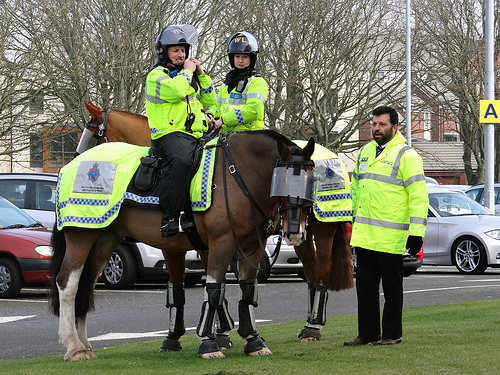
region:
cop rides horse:
[145, 19, 213, 237]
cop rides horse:
[220, 28, 269, 135]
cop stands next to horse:
[345, 106, 427, 346]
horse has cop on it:
[48, 127, 318, 360]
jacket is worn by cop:
[346, 132, 429, 257]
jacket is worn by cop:
[145, 62, 213, 139]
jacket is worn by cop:
[213, 73, 267, 131]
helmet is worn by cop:
[223, 27, 255, 71]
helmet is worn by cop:
[155, 23, 196, 66]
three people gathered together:
[83, 22, 454, 329]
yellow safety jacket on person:
[338, 130, 423, 245]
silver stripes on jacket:
[378, 150, 428, 194]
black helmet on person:
[226, 28, 261, 54]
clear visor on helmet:
[173, 28, 200, 43]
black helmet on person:
[146, 22, 191, 60]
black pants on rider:
[138, 127, 197, 219]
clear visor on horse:
[256, 161, 318, 209]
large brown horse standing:
[33, 133, 319, 362]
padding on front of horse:
[190, 276, 274, 357]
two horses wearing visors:
[41, 97, 355, 367]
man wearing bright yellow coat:
[341, 105, 433, 350]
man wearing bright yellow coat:
[142, 20, 215, 237]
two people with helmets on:
[142, 20, 269, 131]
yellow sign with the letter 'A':
[476, 97, 498, 130]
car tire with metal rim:
[450, 232, 487, 277]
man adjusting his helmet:
[141, 21, 218, 143]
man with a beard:
[363, 102, 404, 157]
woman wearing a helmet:
[214, 30, 271, 132]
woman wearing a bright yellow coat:
[220, 29, 270, 129]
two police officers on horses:
[44, 24, 351, 359]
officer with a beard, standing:
[349, 104, 428, 346]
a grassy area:
[1, 297, 496, 372]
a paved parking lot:
[1, 269, 495, 353]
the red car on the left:
[1, 197, 56, 298]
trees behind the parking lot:
[0, 2, 498, 178]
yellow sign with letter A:
[477, 98, 498, 122]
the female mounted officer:
[213, 28, 270, 129]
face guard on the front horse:
[270, 168, 314, 202]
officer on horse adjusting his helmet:
[150, 24, 219, 234]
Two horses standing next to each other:
[41, 93, 360, 369]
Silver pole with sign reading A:
[464, 4, 498, 217]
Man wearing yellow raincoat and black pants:
[338, 103, 434, 347]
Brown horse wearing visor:
[35, 127, 318, 362]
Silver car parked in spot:
[361, 184, 498, 272]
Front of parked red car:
[0, 193, 72, 300]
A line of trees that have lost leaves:
[1, 0, 498, 184]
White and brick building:
[288, 31, 498, 183]